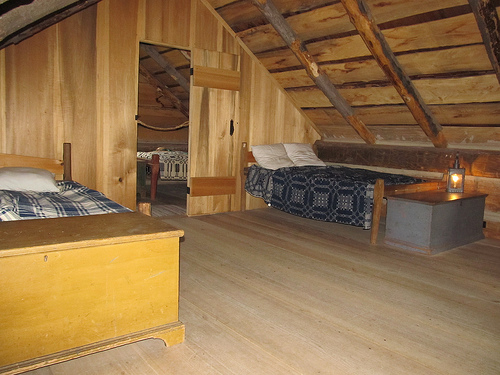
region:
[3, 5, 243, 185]
Walls made of wood.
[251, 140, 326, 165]
White pillows on the bed.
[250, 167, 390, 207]
Blue printed blanket spread on the bed.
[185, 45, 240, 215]
Door made of wood.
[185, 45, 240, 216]
Wooden door matching the walls.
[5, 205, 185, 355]
Wooden trunk at the end of the bed.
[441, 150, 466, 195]
Lit lantern at the end of the bed.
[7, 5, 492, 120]
Ceilings are made of wood.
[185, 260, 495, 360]
Woodfloor is light colored.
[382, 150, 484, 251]
Lantern on a bed trunk.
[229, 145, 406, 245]
wooden bed frame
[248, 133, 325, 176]
two pillows on bed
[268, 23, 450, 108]
wodden rafters in room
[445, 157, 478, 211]
small light at the foot of the bed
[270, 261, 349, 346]
wooden floors in the room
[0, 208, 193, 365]
wood trunk at the end of the bed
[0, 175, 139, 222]
plaid blanket on bed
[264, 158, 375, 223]
blue blanket on bed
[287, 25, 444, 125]
wood paneling on the ceiling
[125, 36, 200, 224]
door is open to room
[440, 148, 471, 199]
small metal lantern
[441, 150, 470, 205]
gray lantern with orange flame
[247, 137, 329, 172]
two fluffy white pillows on a bed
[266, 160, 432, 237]
blue and grey comforter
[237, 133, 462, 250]
full size bed with wooden frame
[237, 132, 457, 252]
bed with blue and grey blanket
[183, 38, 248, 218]
wooden door with black handle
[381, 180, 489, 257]
grey wooden chest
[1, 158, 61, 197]
white pillow on top of plaid comforter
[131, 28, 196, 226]
narrow open doorway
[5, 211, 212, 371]
wood blanket box at foot of bed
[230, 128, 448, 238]
bed with blue patterned blanket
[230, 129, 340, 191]
two white pillows on a bed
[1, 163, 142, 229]
blue and white plaid bedspread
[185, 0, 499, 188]
steeply angled roof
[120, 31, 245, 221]
door open to another bedroom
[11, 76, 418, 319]
bedroom with two beds in it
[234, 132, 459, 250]
wood frame of a bed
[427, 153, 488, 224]
square hurricane lamp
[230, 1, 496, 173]
wood roof beams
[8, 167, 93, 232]
White pillow on bed.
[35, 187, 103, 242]
Blue and white bed spread on bed.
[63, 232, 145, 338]
Light brown chest at foot of bed.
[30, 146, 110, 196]
Light brown head board on bed.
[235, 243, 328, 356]
Light brown wood floor.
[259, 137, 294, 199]
White pillow on bed.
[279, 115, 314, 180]
White pillow on bed.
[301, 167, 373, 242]
Blue bedspread on bed.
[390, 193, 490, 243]
Gray chest at end of bed.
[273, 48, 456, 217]
Angled ceiling in room.